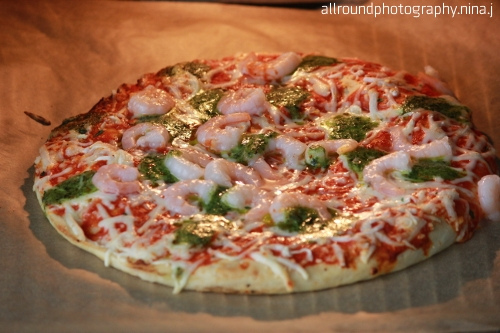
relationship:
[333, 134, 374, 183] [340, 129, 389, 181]
green leaves of basil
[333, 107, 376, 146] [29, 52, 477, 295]
broccoli topping a pizza